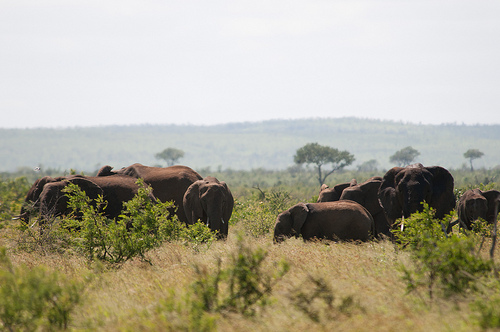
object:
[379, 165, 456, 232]
elephant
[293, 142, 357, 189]
tree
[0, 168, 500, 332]
desert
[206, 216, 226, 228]
white tusks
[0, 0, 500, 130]
sky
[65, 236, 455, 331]
dry vegetation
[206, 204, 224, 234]
trunk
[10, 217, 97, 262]
food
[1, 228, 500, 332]
shrubs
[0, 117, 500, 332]
landscape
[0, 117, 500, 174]
distance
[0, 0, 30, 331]
left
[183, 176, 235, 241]
elephant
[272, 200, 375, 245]
elephant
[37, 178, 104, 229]
elephant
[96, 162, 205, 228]
elephant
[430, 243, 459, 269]
leaves